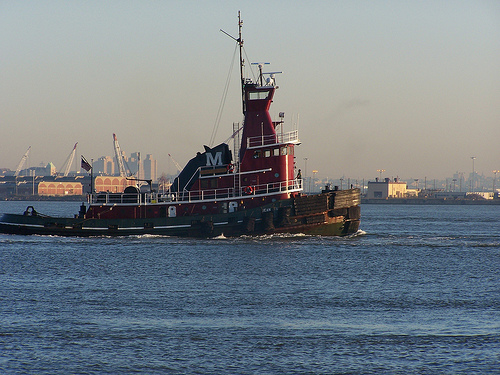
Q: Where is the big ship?
A: In the ocean.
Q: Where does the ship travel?
A: To the right.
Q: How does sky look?
A: Blue and cloudy.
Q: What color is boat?
A: Red and black.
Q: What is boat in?
A: Blue water.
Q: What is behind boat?
A: City in background.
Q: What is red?
A: Fishing boat.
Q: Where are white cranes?
A: Along sea port.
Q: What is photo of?
A: Boat on the water.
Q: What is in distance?
A: Cranes.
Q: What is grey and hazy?
A: The sky.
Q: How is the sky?
A: Clear.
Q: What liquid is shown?
A: Water.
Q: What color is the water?
A: Blue.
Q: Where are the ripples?
A: In water.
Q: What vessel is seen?
A: Ship.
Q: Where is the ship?
A: On water.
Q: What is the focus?
A: Tugboat.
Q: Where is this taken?
A: Ocean.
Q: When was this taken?
A: Daytime.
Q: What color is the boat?
A: Red.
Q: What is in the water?
A: Boat.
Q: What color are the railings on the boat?
A: White.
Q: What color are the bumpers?
A: Black.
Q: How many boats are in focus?
A: 1.